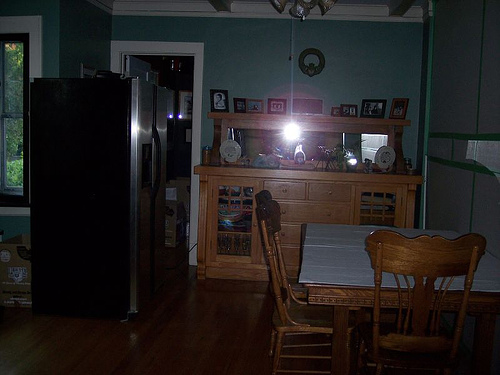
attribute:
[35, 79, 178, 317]
refrigerator — black, stainless steel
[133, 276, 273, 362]
floors — brown, hardwood, shiny, wood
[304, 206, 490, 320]
table — wooden, wood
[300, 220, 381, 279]
cloth — white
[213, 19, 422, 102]
wall — green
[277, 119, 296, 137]
light — glaring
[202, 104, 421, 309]
hutch — brown, oak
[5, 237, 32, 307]
box — cardboard, brown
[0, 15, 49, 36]
trim — white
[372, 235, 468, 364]
chair — wooden, oak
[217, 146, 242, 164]
plate — displayed, on display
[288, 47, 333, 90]
wreath — hanging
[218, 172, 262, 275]
door — glass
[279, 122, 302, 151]
flash — camera flash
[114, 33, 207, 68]
trim — white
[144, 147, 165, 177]
handle — black